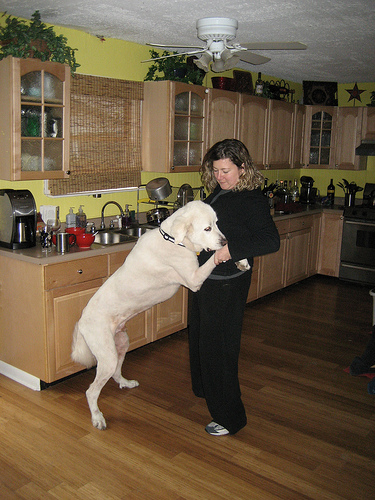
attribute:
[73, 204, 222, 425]
dog — standing, large, white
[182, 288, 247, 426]
pants — black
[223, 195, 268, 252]
shirt — black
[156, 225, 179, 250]
collar — black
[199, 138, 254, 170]
hair — blonde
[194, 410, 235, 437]
sneakers — white, grey, tennis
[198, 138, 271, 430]
woman — dancing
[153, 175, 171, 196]
pots — silver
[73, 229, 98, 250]
bowls — red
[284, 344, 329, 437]
floor — brown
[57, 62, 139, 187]
window — covered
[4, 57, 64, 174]
cabinet — glass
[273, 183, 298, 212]
mixer — black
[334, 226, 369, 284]
stove — silver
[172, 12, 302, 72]
fan — white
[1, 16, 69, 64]
plants — green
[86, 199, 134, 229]
faucet — grey